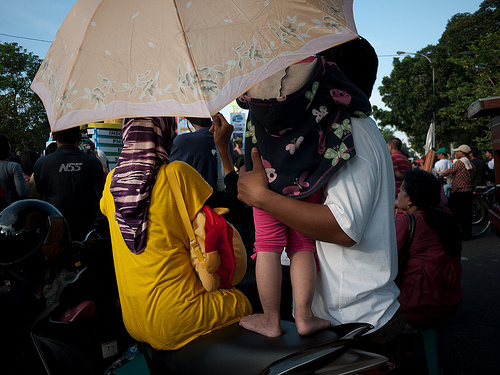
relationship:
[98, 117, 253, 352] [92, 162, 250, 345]
woman on yellow shirt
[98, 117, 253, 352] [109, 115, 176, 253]
woman on scarf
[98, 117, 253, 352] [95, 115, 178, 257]
woman on scarf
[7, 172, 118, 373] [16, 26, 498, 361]
bike on people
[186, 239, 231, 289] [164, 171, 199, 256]
purse has strap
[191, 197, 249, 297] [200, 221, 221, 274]
stuffed animal has arm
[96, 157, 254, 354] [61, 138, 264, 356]
dress on woman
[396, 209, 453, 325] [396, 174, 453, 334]
dress on woman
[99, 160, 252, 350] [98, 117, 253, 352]
dress on woman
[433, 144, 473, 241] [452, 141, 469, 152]
person wearing cap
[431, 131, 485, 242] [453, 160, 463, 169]
person has shoulder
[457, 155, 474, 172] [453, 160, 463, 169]
napkin on shoulder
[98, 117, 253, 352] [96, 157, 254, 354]
woman wearing dress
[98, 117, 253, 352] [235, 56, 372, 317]
woman next to child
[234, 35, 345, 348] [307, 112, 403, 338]
man wearing t-shirt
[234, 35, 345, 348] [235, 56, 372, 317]
man holding child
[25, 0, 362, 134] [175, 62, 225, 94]
umbrella has leaves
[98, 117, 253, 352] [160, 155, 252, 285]
woman wearing bag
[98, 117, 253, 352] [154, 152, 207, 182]
woman has shoulder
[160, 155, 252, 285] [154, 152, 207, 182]
bag on shoulder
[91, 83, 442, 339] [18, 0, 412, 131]
family under umbrella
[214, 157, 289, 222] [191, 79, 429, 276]
hand on person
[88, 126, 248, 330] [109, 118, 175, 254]
woman has hair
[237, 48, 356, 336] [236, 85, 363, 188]
child wearing hoodie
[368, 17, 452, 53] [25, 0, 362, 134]
sky behind umbrella